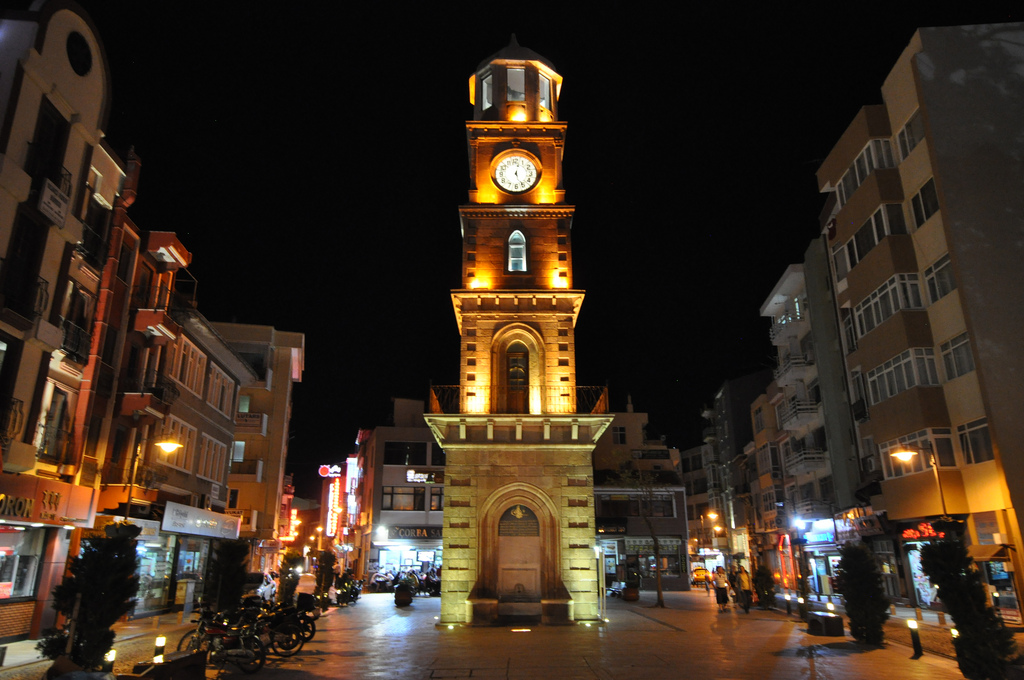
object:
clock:
[468, 148, 544, 207]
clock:
[492, 153, 542, 195]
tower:
[435, 45, 619, 635]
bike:
[184, 610, 264, 669]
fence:
[184, 595, 321, 678]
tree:
[200, 539, 247, 646]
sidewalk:
[25, 528, 356, 665]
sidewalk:
[39, 539, 348, 678]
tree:
[50, 522, 138, 670]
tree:
[310, 535, 338, 603]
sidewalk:
[112, 444, 358, 680]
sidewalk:
[2, 384, 393, 680]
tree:
[46, 505, 155, 680]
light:
[890, 420, 917, 503]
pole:
[889, 382, 952, 635]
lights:
[419, 110, 595, 675]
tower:
[444, 203, 581, 355]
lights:
[339, 511, 432, 630]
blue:
[381, 513, 431, 561]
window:
[485, 233, 532, 314]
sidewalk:
[247, 581, 857, 680]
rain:
[440, 624, 585, 680]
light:
[881, 440, 927, 482]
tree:
[24, 498, 145, 680]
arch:
[493, 492, 545, 551]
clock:
[484, 248, 575, 288]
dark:
[257, 209, 293, 242]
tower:
[503, 248, 583, 387]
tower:
[424, 241, 630, 470]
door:
[476, 459, 556, 680]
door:
[104, 529, 254, 680]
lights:
[788, 505, 851, 558]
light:
[378, 509, 654, 661]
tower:
[455, 324, 638, 680]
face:
[476, 138, 564, 206]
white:
[469, 203, 611, 243]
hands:
[506, 161, 534, 188]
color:
[440, 205, 612, 322]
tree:
[33, 511, 142, 680]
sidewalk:
[33, 576, 502, 680]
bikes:
[135, 524, 349, 680]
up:
[238, 572, 255, 665]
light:
[885, 440, 921, 477]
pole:
[918, 427, 946, 514]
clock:
[487, 146, 548, 198]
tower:
[424, 55, 613, 628]